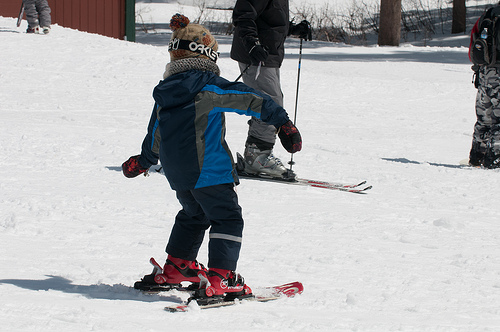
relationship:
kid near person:
[128, 7, 284, 303] [224, 5, 341, 195]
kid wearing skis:
[128, 7, 284, 303] [135, 257, 310, 322]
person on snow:
[224, 5, 341, 195] [2, 2, 484, 330]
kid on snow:
[128, 7, 284, 303] [2, 2, 484, 330]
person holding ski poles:
[225, 2, 360, 194] [284, 25, 308, 109]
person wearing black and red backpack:
[460, 4, 483, 153] [465, 12, 484, 62]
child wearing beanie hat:
[119, 12, 302, 300] [164, 11, 219, 61]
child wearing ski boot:
[119, 12, 302, 300] [162, 251, 209, 284]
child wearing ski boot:
[119, 12, 302, 300] [205, 266, 253, 299]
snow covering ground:
[2, 2, 484, 330] [2, 2, 484, 330]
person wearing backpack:
[468, 1, 483, 171] [468, 5, 484, 70]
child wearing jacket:
[119, 12, 302, 300] [138, 68, 288, 190]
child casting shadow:
[119, 12, 302, 300] [2, 272, 189, 303]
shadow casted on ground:
[2, 272, 189, 303] [2, 2, 484, 330]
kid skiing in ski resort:
[120, 11, 303, 296] [1, 1, 484, 330]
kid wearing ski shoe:
[120, 11, 303, 296] [162, 250, 209, 281]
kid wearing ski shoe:
[120, 11, 303, 296] [204, 265, 252, 300]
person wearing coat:
[118, 11, 303, 299] [138, 68, 288, 190]